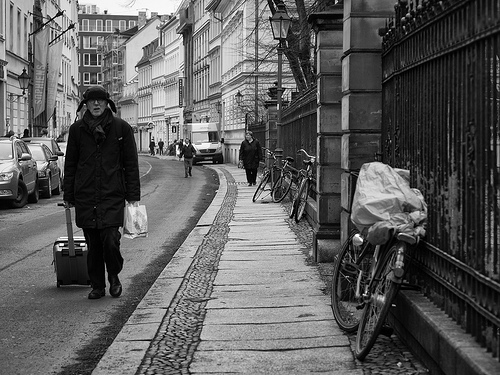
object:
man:
[50, 85, 142, 301]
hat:
[76, 85, 117, 114]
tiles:
[194, 336, 350, 351]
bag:
[122, 201, 148, 240]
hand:
[128, 200, 140, 207]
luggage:
[50, 203, 92, 288]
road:
[0, 298, 88, 375]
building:
[77, 0, 148, 85]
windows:
[82, 53, 102, 67]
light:
[269, 2, 293, 182]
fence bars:
[377, 0, 498, 356]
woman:
[239, 131, 263, 186]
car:
[0, 136, 39, 208]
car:
[28, 142, 62, 199]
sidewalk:
[187, 284, 333, 374]